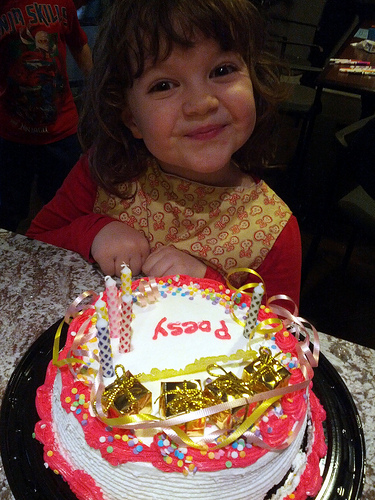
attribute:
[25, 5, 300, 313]
girl — small, smiling, young, little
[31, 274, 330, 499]
cake — decorated, pink, white, small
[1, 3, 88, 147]
shirt — red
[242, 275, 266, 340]
candle — green, black, unlit, white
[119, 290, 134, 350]
candle — red, white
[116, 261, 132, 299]
candle — yellow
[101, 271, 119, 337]
candle — pink, white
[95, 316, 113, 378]
candle — blue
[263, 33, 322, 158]
chair — gray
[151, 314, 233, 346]
word — red, pink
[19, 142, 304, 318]
shirt — red, yellow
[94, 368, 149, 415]
box — gold, small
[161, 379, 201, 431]
box — gold, small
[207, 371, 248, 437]
box — gold, small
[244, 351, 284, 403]
box — gold, small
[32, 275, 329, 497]
frosting — pink, white, red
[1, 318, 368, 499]
platter — black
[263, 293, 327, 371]
ribbon — pastel, gold, pink, curly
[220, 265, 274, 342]
ribbon — curly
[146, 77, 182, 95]
eye — bright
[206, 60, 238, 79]
eye — bright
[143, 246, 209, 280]
hand — curled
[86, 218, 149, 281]
hand — curled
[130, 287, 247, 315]
sprinkles — circular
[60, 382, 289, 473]
sprinkles — circular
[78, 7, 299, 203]
hair — brunette